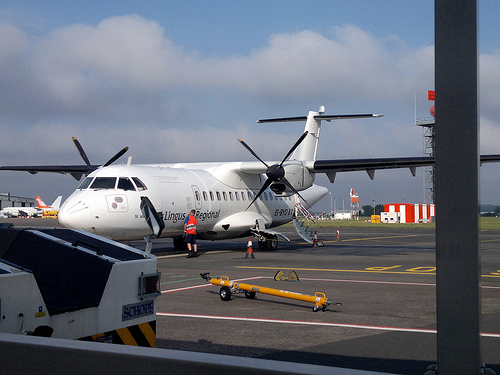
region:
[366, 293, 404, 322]
Small part of the black runway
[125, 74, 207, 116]
Medium part of partly cloudy sky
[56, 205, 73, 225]
Nose of the white airplane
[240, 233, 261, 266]
Orange, white, and black cone on airfield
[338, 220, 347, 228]
Small patch of green grass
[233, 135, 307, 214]
Left propeller on airplane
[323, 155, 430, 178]
Left black wing on airplane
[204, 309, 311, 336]
White and red solid line on runway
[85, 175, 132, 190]
Three front windows on airplane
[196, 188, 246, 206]
Few of the passengers windows on the airplane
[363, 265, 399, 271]
the yellow P on the tarmac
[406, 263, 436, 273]
the yellow O on the tarmac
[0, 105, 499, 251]
the airplane on the tarmac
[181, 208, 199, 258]
the man next to the airplane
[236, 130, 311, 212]
the propeller on the airplane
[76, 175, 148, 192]
the windows to the cockpit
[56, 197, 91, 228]
the nose on the airplane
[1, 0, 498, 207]
the clouds in the blue sky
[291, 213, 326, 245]
the stairs to the airplane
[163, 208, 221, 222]
the words on the side of the airplane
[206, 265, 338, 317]
A yellow pole with wheels on the runway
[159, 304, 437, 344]
A thin white line painted on the runway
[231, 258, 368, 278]
A yellow line on the ground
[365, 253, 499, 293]
Large yellow letters painted on the ground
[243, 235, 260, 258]
An orange and white traffic cone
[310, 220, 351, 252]
Traffic cones by the entrance of the plane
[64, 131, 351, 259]
A large aircraft on the runway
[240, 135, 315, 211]
Side propeller of the aircraft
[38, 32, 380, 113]
Thick grey clouds in the sky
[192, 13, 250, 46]
A patch of clear blue sky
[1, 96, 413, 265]
a white plane on an airport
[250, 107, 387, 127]
a black horizontal stabilizer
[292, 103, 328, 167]
white plane stabilizer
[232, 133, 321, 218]
a propeller on right wing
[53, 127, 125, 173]
a propeller on left wing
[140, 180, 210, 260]
man in front of airplane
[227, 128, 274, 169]
tip of propellers is yellow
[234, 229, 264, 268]
a cone in front of plane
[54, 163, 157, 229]
windows on cockpit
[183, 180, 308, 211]
windows on side of plane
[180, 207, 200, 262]
a man wears special gear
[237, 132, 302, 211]
the plane's propeller was black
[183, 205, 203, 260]
an orange vest would ensure that he could be seen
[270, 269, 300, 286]
the landing gear blocks had been removed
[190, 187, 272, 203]
the plane had small porthole-style windows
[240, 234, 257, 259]
a caution cone remains until the plane is ready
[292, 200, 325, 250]
the plane's staircase was open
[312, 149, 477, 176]
each wing of the plane was black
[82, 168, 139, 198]
the cockpit was wear the captain would sit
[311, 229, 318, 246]
a caution cone drew attention to the stairway